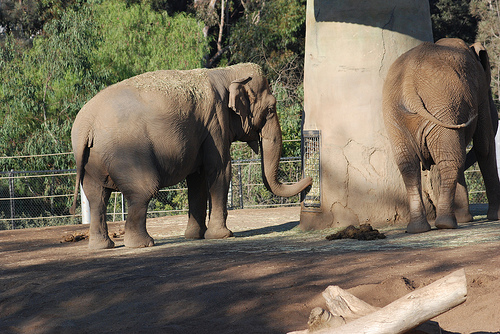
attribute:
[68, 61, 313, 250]
elephant — large, walking, fat, dusty, feeding, adult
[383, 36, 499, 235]
elephant — large, walking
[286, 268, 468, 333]
branch — broken, down, wood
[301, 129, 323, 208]
feeder — secured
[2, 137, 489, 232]
fence — white, metal, security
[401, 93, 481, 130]
tail — swinging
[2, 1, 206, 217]
tree — green, large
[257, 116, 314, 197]
trunk — coiled, curled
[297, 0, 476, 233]
pillar — wide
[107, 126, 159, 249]
leg — short, rear